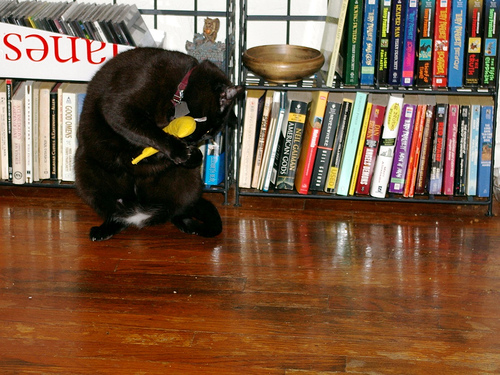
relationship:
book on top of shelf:
[335, 0, 360, 87] [243, 68, 495, 97]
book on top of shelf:
[360, 1, 377, 86] [243, 68, 495, 97]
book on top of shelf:
[376, 0, 391, 87] [243, 68, 495, 97]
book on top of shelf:
[389, 2, 403, 88] [243, 68, 495, 97]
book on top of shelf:
[400, 0, 418, 87] [243, 68, 495, 97]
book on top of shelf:
[416, 0, 433, 88] [243, 68, 495, 97]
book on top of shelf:
[433, 1, 450, 88] [243, 68, 495, 97]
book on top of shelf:
[448, 1, 465, 88] [243, 68, 495, 97]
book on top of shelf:
[462, 1, 484, 88] [243, 68, 495, 97]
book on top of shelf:
[480, 0, 496, 88] [243, 68, 495, 97]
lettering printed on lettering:
[3, 31, 121, 64] [3, 31, 121, 64]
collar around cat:
[169, 62, 197, 111] [72, 44, 244, 243]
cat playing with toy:
[72, 44, 244, 243] [129, 115, 198, 165]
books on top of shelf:
[237, 93, 493, 198] [236, 183, 491, 207]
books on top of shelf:
[2, 77, 224, 186] [1, 175, 225, 194]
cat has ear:
[72, 44, 244, 243] [222, 80, 247, 103]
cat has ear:
[72, 44, 244, 243] [228, 106, 242, 128]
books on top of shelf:
[321, 1, 498, 89] [243, 68, 495, 97]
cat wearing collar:
[72, 44, 244, 243] [169, 62, 197, 111]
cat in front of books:
[72, 44, 244, 243] [2, 77, 224, 186]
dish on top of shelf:
[241, 42, 325, 85] [243, 68, 495, 97]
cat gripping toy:
[72, 44, 244, 243] [129, 115, 198, 165]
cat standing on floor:
[72, 44, 244, 243] [0, 180, 499, 374]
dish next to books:
[241, 42, 325, 85] [321, 1, 498, 89]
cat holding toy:
[72, 44, 244, 243] [129, 115, 198, 165]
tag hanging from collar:
[173, 96, 190, 119] [169, 62, 197, 111]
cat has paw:
[72, 44, 244, 243] [168, 137, 190, 166]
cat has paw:
[72, 44, 244, 243] [183, 145, 203, 169]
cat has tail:
[72, 44, 244, 243] [186, 195, 224, 236]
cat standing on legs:
[72, 44, 244, 243] [80, 207, 202, 237]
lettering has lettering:
[3, 31, 121, 64] [3, 31, 121, 64]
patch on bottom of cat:
[110, 201, 155, 230] [72, 44, 244, 243]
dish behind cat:
[241, 42, 325, 85] [72, 44, 244, 243]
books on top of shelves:
[237, 93, 493, 198] [1, 0, 499, 217]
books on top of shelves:
[2, 77, 224, 186] [1, 0, 499, 217]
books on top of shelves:
[321, 1, 498, 89] [1, 0, 499, 217]